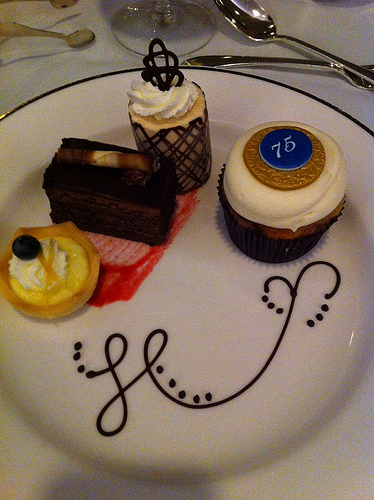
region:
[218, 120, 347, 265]
cupcake with white icing and a blue 75 on top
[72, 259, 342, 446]
design on plate drawn in chocolate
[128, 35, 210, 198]
white pastry with whipped cream and chocolate on the side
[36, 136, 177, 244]
rich chocolate cake with chocolate iceing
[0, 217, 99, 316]
lemon blueberry tart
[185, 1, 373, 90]
silver fork and spoon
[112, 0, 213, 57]
base of a goblet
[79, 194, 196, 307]
strawberry gel smeared under pastries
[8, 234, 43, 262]
whole fresh blueberry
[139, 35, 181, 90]
chocolate flourish on pastry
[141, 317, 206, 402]
frosting used to make a design on the plate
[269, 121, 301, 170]
75 is on a blue circle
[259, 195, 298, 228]
frosting is vanilla on the cupcake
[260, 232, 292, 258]
black wrapper on the cupcake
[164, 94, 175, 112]
whip cream on the dessert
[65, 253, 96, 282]
custard in the dessert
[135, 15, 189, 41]
stem of the glass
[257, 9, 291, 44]
spoon next to the glass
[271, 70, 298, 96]
gold trim around the plate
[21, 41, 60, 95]
table cloth is white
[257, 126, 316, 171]
a blue disk with the number 75 in white lettering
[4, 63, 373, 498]
a plate full of sweets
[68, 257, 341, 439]
a fancy design on a white plate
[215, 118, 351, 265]
a cupcake with white frosting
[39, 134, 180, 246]
a slice of chocolate cake with chocolate frosting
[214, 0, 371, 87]
a spoon resting on the table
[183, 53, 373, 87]
a fork on a table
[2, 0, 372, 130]
a white tablecloth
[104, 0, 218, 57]
a clear glass base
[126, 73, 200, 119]
whipped cream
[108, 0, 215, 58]
base of a wine glass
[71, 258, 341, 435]
decorative chocolate swirl on desert plate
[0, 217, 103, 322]
small cream tart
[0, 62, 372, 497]
white plate with gold trim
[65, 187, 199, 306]
smear of red juice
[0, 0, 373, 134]
white cloth tablecloth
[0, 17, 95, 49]
small spoon on the left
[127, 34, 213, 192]
tall desert cake with whipped cream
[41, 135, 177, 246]
square of chocolate mousse cake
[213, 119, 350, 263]
cupcake with a blue 75 decoration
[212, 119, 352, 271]
this is a cake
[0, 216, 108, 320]
this is a cake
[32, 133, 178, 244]
this is a cake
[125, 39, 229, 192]
this is a cake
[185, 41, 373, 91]
this is a spoon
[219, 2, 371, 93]
this is a spoon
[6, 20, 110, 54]
this is a spoon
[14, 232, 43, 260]
decoration on a cake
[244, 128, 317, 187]
decoration on a cake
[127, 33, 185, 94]
decoration on a cake